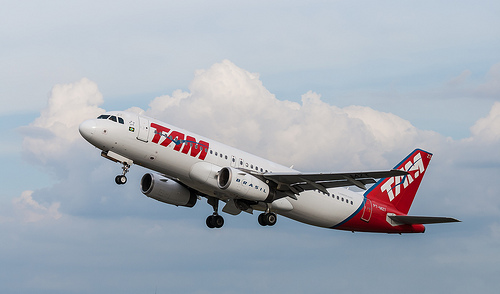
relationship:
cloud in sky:
[1, 64, 498, 225] [0, 1, 499, 292]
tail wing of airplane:
[388, 216, 460, 225] [78, 111, 460, 235]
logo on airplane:
[149, 123, 211, 161] [78, 111, 460, 235]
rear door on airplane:
[360, 199, 373, 222] [78, 111, 460, 235]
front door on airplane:
[136, 118, 149, 143] [78, 111, 460, 235]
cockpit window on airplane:
[97, 114, 124, 124] [78, 111, 460, 235]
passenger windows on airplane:
[315, 191, 354, 206] [78, 111, 460, 235]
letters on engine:
[234, 179, 267, 194] [216, 167, 277, 204]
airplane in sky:
[78, 111, 460, 235] [0, 1, 499, 292]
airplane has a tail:
[78, 111, 460, 235] [364, 148, 434, 214]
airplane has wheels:
[78, 111, 460, 235] [114, 174, 124, 185]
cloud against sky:
[1, 64, 498, 225] [0, 1, 499, 292]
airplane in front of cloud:
[78, 111, 460, 235] [1, 64, 498, 225]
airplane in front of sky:
[78, 111, 460, 235] [0, 1, 499, 292]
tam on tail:
[380, 154, 425, 202] [364, 148, 434, 214]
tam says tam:
[380, 154, 425, 202] [382, 154, 425, 201]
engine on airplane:
[139, 174, 197, 208] [78, 111, 460, 235]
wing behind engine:
[253, 170, 407, 201] [216, 167, 277, 204]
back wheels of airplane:
[205, 214, 275, 228] [78, 111, 460, 235]